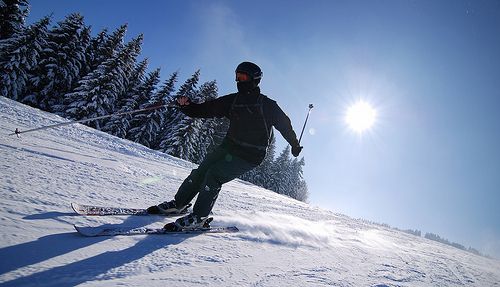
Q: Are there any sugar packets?
A: No, there are no sugar packets.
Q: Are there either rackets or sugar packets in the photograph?
A: No, there are no sugar packets or rackets.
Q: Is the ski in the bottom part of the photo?
A: Yes, the ski is in the bottom of the image.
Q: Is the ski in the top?
A: No, the ski is in the bottom of the image.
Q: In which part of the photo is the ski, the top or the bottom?
A: The ski is in the bottom of the image.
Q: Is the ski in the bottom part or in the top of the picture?
A: The ski is in the bottom of the image.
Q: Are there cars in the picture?
A: No, there are no cars.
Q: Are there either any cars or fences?
A: No, there are no cars or fences.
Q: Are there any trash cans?
A: No, there are no trash cans.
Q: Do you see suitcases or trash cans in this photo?
A: No, there are no trash cans or suitcases.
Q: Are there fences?
A: No, there are no fences.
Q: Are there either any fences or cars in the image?
A: No, there are no fences or cars.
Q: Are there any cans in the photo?
A: No, there are no cans.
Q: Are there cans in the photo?
A: No, there are no cans.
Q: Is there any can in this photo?
A: No, there are no cans.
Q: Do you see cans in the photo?
A: No, there are no cans.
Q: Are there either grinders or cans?
A: No, there are no cans or grinders.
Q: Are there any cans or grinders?
A: No, there are no cans or grinders.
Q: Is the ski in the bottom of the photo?
A: Yes, the ski is in the bottom of the image.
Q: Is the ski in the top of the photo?
A: No, the ski is in the bottom of the image.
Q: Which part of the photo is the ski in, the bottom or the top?
A: The ski is in the bottom of the image.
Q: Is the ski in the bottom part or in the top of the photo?
A: The ski is in the bottom of the image.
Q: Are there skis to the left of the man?
A: Yes, there is a ski to the left of the man.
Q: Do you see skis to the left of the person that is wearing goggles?
A: Yes, there is a ski to the left of the man.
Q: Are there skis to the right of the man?
A: No, the ski is to the left of the man.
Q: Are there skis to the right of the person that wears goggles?
A: No, the ski is to the left of the man.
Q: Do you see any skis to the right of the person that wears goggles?
A: No, the ski is to the left of the man.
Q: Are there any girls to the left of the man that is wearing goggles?
A: No, there is a ski to the left of the man.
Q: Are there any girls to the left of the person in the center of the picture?
A: No, there is a ski to the left of the man.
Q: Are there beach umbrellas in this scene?
A: No, there are no beach umbrellas.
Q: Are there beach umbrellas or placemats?
A: No, there are no beach umbrellas or placemats.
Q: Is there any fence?
A: No, there are no fences.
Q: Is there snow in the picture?
A: Yes, there is snow.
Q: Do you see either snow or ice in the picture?
A: Yes, there is snow.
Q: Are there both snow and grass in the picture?
A: No, there is snow but no grass.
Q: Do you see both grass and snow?
A: No, there is snow but no grass.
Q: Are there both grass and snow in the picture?
A: No, there is snow but no grass.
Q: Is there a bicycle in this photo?
A: No, there are no bicycles.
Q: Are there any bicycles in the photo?
A: No, there are no bicycles.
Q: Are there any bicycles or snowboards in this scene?
A: No, there are no bicycles or snowboards.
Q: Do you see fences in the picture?
A: No, there are no fences.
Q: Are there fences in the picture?
A: No, there are no fences.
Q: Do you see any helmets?
A: Yes, there is a helmet.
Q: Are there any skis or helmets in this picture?
A: Yes, there is a helmet.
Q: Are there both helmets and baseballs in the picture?
A: No, there is a helmet but no baseballs.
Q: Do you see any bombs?
A: No, there are no bombs.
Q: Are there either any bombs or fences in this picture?
A: No, there are no bombs or fences.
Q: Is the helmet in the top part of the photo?
A: Yes, the helmet is in the top of the image.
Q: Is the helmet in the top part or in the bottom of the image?
A: The helmet is in the top of the image.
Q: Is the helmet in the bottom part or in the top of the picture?
A: The helmet is in the top of the image.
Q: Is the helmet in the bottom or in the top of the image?
A: The helmet is in the top of the image.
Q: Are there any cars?
A: No, there are no cars.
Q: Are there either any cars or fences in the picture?
A: No, there are no cars or fences.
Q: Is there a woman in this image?
A: No, there are no women.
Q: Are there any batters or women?
A: No, there are no women or batters.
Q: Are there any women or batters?
A: No, there are no women or batters.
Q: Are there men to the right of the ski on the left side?
A: Yes, there is a man to the right of the ski.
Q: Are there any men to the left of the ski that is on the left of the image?
A: No, the man is to the right of the ski.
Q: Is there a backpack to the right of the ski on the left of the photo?
A: No, there is a man to the right of the ski.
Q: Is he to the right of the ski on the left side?
A: Yes, the man is to the right of the ski.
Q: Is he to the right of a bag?
A: No, the man is to the right of the ski.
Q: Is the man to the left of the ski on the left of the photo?
A: No, the man is to the right of the ski.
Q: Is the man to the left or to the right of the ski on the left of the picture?
A: The man is to the right of the ski.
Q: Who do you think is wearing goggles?
A: The man is wearing goggles.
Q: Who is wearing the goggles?
A: The man is wearing goggles.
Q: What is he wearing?
A: The man is wearing goggles.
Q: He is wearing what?
A: The man is wearing goggles.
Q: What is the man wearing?
A: The man is wearing goggles.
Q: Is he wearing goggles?
A: Yes, the man is wearing goggles.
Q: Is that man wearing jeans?
A: No, the man is wearing goggles.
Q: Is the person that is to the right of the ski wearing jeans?
A: No, the man is wearing goggles.